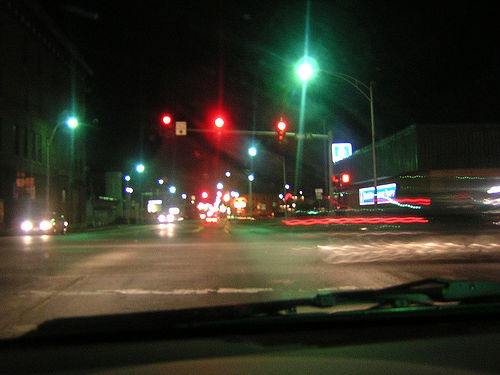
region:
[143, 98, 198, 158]
traffic light on left is red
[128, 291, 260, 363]
windshield wiper on windshield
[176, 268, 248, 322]
white line on street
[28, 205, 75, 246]
bright headlamps of car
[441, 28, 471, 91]
sky is black and clear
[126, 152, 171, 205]
second street light on left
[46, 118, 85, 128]
first street light on left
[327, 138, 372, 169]
blue and white electric sign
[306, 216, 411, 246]
red blur from brake light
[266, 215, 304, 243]
windshield of car driving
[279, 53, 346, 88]
a green traffic light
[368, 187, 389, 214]
the bottom of the street light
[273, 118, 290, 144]
red traffic light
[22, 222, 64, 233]
the car's headlights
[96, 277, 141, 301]
a white line in the road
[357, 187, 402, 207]
a blue neon sign in the distance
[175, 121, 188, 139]
a white traffic sign in the distance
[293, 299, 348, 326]
the windshield wipers on the car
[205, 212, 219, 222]
tail light in the distance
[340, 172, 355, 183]
a orange walking sign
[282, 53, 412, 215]
a poe light over a street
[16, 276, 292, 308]
a white line on a black top surface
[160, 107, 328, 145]
red lights on a pole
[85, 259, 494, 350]
a windshield wipers on a car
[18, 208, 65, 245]
a car with lights on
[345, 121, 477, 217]
a building on the corner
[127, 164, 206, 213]
a row of street lights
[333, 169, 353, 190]
a red walking light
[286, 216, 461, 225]
a blur of red lights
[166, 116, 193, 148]
a sign on a pole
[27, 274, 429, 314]
black windshield wiper on windshield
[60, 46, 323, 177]
three glowing street lights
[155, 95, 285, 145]
three red traffic lights on same pole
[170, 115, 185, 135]
black and white street sign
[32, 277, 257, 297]
white line painted on road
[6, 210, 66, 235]
car stopped at intersection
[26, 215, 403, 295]
intersection in front of car window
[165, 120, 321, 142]
pole three traffic lights are on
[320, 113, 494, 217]
building on right side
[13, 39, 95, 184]
building on right side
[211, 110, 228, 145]
traffic signal shows red light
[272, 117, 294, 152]
traffic signal shows red light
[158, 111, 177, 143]
traffic signal shows red light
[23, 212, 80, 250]
vehicle with head lights on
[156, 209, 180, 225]
vehicle with head lights on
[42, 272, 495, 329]
black windshield wiper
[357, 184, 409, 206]
neon sign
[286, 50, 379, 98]
lit up street light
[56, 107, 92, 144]
lit up street light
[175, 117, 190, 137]
traffic sign with green circle in it